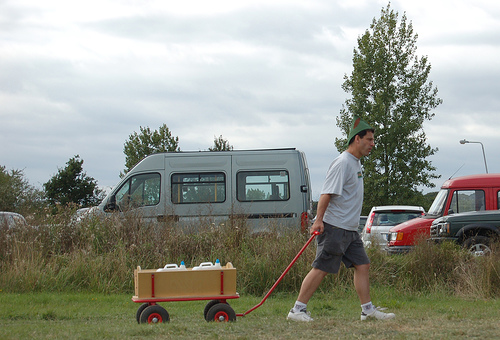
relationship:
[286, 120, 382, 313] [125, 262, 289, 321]
man pulling wagon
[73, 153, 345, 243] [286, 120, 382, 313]
van behind man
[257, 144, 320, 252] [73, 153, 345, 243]
back of van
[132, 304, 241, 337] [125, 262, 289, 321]
wheels on wagon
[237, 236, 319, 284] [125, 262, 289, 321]
pole connected to wagon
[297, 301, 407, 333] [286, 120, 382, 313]
shoes of man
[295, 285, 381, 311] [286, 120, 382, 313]
socks of man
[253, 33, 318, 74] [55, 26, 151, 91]
clouds in sky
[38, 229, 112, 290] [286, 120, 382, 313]
grasses behind man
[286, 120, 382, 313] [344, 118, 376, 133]
man with hat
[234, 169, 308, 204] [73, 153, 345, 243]
window of van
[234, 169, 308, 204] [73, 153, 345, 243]
window in van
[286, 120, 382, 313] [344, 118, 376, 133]
man in hat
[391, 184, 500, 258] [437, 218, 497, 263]
red vehicle behind black car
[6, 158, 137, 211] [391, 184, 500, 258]
trees behind cars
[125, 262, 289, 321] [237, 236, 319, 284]
wagon with pole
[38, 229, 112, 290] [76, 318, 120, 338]
grasses by road